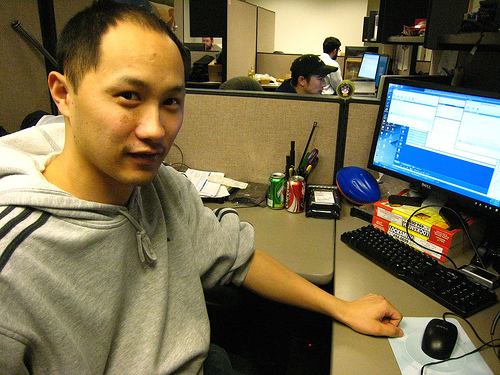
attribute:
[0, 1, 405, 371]
man — looking, asian, sitting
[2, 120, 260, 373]
hoodie — gray, grey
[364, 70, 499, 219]
computer monitor — on, bright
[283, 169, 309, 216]
soda can — red, aluminum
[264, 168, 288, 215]
soda can — green, aluminum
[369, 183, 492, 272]
books — phone books, yellow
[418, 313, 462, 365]
mouse — black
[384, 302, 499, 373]
mouse pad — grey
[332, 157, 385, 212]
football — blue, foam, red, orange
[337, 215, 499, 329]
keyboard — black, slim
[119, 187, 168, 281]
drawstring — gray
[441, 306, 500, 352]
wire — black